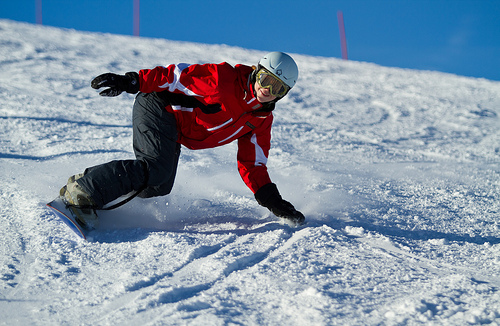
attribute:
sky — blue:
[2, 1, 499, 83]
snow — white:
[0, 21, 499, 325]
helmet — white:
[259, 53, 305, 87]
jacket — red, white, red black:
[143, 65, 276, 200]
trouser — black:
[83, 92, 180, 214]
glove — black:
[92, 67, 139, 100]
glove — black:
[254, 180, 305, 222]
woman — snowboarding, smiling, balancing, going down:
[58, 52, 307, 237]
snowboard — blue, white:
[47, 191, 88, 242]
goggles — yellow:
[254, 72, 289, 97]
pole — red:
[332, 11, 356, 63]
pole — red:
[123, 0, 152, 41]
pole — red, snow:
[30, 2, 47, 31]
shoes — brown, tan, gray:
[64, 173, 99, 226]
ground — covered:
[2, 17, 499, 325]